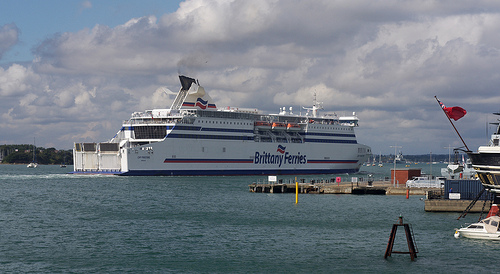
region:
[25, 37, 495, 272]
large boat int he middle of water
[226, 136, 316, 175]
logo on side of boat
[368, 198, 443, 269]
buoy in the middle of water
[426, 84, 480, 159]
red flag on flag pole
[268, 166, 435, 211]
wooden pier on water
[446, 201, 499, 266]
small boat on the water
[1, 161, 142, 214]
white water wake behind boat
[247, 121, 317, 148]
life boats on ship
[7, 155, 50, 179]
small craft in water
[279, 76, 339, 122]
antennas on cruise ship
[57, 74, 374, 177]
a large red, white and blue boat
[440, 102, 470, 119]
a red flag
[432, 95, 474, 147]
a long flag pole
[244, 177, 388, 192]
a brown wooden dock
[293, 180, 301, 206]
a long yellow pole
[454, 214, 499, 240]
a small white boat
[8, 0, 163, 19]
part of a blue sky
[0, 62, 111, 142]
a section of white clouds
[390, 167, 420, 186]
a small red brick building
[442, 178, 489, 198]
a blue container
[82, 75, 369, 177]
a red white and blue cruise ship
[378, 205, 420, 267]
a rusted old buoy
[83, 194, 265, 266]
calm rippling waters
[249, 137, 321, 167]
Brittany Ferries on the side of the ship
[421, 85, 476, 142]
a red flag on a pole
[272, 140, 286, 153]
a red white and blue flag emblem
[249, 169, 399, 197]
a brown boat pier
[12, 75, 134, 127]
billowing grey clouds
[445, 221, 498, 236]
a small personal boat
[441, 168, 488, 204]
a blue crate on the pier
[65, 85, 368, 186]
White ship floating in the water with blue and red lines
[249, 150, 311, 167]
Blue words on a white ship reading "Brittany Ferries"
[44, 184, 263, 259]
Calm blue water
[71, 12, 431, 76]
Blue sky thick with clouds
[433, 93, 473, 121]
Red flag flying on a black flag pole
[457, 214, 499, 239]
White boat in the water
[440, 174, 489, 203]
Blue shipping container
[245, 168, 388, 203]
Gray concrete dock jutting into the water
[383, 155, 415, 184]
Red shipping container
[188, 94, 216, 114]
Blue and red logo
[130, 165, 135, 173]
front part of a ship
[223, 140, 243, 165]
side of a ship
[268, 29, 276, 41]
part of a cloud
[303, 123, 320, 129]
inside of a ship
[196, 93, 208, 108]
flag on a ship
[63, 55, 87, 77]
part of the clouds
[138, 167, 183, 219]
part of the water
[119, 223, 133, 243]
section of the water